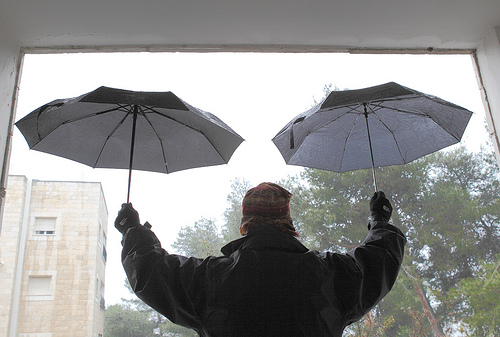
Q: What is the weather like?
A: It is overcast.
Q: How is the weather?
A: It is overcast.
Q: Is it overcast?
A: Yes, it is overcast.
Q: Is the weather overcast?
A: Yes, it is overcast.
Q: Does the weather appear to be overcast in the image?
A: Yes, it is overcast.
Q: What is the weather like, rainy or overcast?
A: It is overcast.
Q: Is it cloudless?
A: No, it is overcast.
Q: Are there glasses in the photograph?
A: No, there are no glasses.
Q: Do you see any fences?
A: No, there are no fences.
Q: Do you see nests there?
A: No, there are no nests.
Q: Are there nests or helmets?
A: No, there are no nests or helmets.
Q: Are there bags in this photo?
A: No, there are no bags.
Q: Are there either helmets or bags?
A: No, there are no bags or helmets.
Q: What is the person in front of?
A: The person is in front of the building.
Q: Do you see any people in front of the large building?
A: Yes, there is a person in front of the building.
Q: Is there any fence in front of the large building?
A: No, there is a person in front of the building.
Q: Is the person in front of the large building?
A: Yes, the person is in front of the building.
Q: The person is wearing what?
A: The person is wearing a jacket.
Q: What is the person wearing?
A: The person is wearing a jacket.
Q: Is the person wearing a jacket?
A: Yes, the person is wearing a jacket.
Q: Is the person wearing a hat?
A: No, the person is wearing a jacket.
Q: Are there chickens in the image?
A: No, there are no chickens.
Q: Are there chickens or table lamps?
A: No, there are no chickens or table lamps.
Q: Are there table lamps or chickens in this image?
A: No, there are no chickens or table lamps.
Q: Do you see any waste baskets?
A: No, there are no waste baskets.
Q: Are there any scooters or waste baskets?
A: No, there are no waste baskets or scooters.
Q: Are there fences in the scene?
A: No, there are no fences.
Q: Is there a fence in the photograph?
A: No, there are no fences.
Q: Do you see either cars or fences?
A: No, there are no fences or cars.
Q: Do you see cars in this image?
A: No, there are no cars.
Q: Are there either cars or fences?
A: No, there are no cars or fences.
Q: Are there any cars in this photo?
A: No, there are no cars.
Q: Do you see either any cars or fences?
A: No, there are no cars or fences.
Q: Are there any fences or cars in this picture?
A: No, there are no cars or fences.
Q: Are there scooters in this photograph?
A: No, there are no scooters.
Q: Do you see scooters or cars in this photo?
A: No, there are no scooters or cars.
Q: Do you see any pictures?
A: No, there are no pictures.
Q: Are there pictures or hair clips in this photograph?
A: No, there are no pictures or hair clips.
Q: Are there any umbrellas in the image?
A: Yes, there is an umbrella.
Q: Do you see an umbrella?
A: Yes, there is an umbrella.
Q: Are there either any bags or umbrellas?
A: Yes, there is an umbrella.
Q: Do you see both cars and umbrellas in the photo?
A: No, there is an umbrella but no cars.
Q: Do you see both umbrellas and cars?
A: No, there is an umbrella but no cars.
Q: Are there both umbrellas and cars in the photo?
A: No, there is an umbrella but no cars.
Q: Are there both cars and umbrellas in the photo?
A: No, there is an umbrella but no cars.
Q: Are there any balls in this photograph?
A: No, there are no balls.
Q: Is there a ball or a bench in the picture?
A: No, there are no balls or benches.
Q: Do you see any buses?
A: No, there are no buses.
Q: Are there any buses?
A: No, there are no buses.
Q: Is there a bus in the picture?
A: No, there are no buses.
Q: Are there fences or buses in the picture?
A: No, there are no buses or fences.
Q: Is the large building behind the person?
A: Yes, the building is behind the person.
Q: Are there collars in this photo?
A: Yes, there is a collar.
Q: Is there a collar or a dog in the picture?
A: Yes, there is a collar.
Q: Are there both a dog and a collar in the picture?
A: No, there is a collar but no dogs.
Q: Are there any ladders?
A: No, there are no ladders.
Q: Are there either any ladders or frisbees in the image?
A: No, there are no ladders or frisbees.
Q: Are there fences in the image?
A: No, there are no fences.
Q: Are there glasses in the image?
A: No, there are no glasses.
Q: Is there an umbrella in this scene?
A: Yes, there is an umbrella.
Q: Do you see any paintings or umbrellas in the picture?
A: Yes, there is an umbrella.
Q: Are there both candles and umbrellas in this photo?
A: No, there is an umbrella but no candles.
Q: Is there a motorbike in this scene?
A: No, there are no motorcycles.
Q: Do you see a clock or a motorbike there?
A: No, there are no motorcycles or clocks.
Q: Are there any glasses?
A: No, there are no glasses.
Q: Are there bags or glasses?
A: No, there are no glasses or bags.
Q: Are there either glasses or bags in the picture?
A: No, there are no glasses or bags.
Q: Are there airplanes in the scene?
A: No, there are no airplanes.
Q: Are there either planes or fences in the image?
A: No, there are no planes or fences.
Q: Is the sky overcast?
A: Yes, the sky is overcast.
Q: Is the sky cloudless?
A: No, the sky is overcast.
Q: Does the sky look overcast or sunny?
A: The sky is overcast.